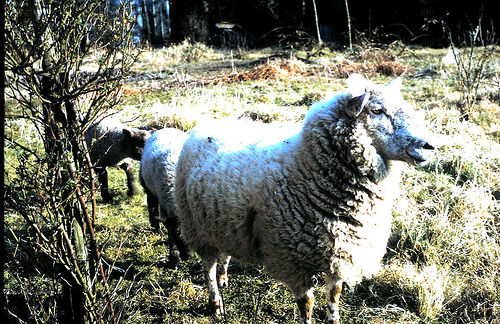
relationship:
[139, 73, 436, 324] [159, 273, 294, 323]
lamb standing in grass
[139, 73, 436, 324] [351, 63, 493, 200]
lamb on grass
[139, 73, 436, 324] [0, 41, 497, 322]
lamb on grass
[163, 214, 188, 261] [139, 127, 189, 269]
leg of sheep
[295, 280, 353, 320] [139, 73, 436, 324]
legs of lamb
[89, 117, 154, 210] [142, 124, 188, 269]
cat behind lamb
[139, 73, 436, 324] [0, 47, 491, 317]
lamb standing in grass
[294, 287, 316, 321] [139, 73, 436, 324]
leg on lamb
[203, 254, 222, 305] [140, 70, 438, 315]
leg of a sheep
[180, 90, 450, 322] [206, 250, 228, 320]
lamb has legs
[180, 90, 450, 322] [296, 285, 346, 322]
lamb has legs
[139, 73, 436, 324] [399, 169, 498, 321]
lamb standing in grass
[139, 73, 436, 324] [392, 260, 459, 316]
lamb standing in grass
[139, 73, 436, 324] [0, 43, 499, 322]
lamb on green grass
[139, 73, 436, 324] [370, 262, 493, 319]
lamb on grass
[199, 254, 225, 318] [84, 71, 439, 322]
leg on sheep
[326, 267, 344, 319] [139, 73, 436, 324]
leg on lamb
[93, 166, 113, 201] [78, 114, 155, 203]
leg on sheep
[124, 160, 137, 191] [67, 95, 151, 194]
leg on sheep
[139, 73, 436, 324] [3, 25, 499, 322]
lamb in pasture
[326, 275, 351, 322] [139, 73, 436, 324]
leg on lamb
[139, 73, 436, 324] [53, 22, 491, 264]
lamb on grass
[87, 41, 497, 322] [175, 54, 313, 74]
grass by log